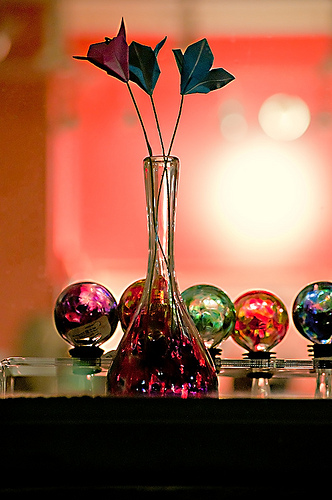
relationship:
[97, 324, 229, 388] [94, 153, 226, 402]
base on vase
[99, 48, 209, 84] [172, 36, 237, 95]
paper make flower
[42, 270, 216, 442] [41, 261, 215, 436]
bulbs and vase